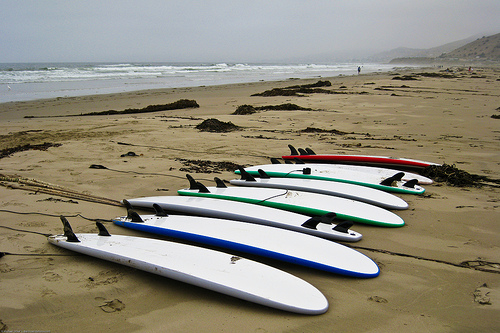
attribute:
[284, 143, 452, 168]
surfboard — red, white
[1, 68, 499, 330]
beach — sandy, light brown, brown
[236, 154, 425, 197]
surfboard — green, white, upsidedown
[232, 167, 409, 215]
surfboard — gray, white, upsidedown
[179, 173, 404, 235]
surfboard — green, white, upsidedown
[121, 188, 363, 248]
surfboard — gray, white, laying down, upsidedown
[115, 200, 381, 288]
surfboard — blue, white, upsidedown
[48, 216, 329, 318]
surfboard — gray, white, upsidedown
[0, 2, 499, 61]
sky — dark, hazy, gray, grayish, blue, overcast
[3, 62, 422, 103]
water — calm, blue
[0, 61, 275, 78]
wave — white, choppy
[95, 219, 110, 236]
knob — black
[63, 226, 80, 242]
knob — black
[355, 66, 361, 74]
person — distant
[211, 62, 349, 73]
wave — choppy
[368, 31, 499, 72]
hill — distant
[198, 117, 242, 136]
seaweed — piled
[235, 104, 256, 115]
seaweed — piled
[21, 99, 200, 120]
seaweed — piled